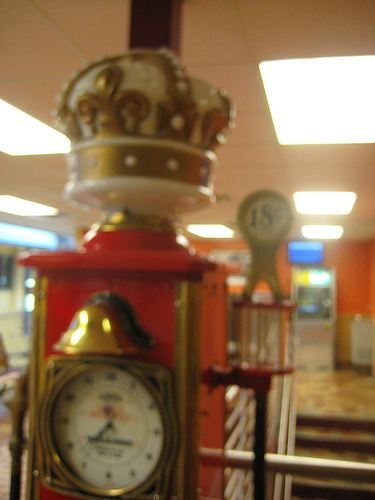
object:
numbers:
[60, 393, 74, 449]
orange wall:
[332, 244, 375, 319]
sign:
[236, 189, 292, 305]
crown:
[53, 45, 235, 215]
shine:
[101, 316, 111, 333]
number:
[250, 202, 273, 227]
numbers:
[107, 372, 116, 380]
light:
[301, 224, 344, 241]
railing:
[191, 413, 372, 490]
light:
[257, 55, 374, 146]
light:
[0, 195, 58, 221]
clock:
[34, 354, 180, 499]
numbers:
[106, 472, 110, 478]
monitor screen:
[287, 241, 323, 264]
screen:
[297, 286, 330, 319]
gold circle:
[32, 353, 177, 499]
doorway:
[290, 258, 336, 373]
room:
[0, 0, 375, 500]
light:
[0, 223, 59, 252]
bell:
[53, 292, 157, 356]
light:
[293, 191, 357, 215]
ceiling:
[0, 0, 375, 247]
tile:
[0, 0, 86, 87]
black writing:
[87, 436, 131, 446]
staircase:
[292, 413, 374, 498]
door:
[288, 260, 336, 367]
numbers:
[64, 392, 74, 401]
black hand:
[88, 415, 114, 440]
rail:
[200, 447, 374, 483]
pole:
[252, 386, 270, 500]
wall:
[188, 240, 289, 294]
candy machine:
[4, 231, 296, 500]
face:
[50, 371, 164, 491]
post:
[232, 188, 297, 365]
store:
[0, 0, 375, 500]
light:
[71, 310, 89, 345]